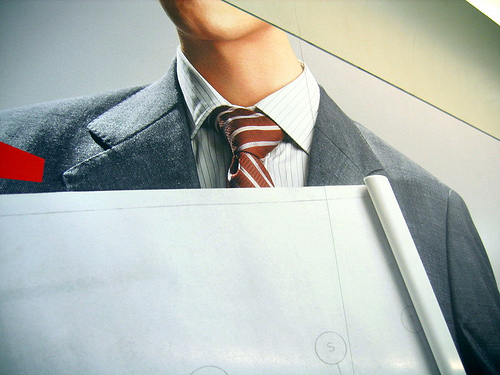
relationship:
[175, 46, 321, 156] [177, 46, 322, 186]
collar of shirt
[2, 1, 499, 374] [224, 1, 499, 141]
ad on a wall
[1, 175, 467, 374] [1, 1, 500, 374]
paper held by man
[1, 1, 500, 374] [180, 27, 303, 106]
man has a neck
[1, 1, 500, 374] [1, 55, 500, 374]
man in a suit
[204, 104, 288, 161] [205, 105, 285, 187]
knot on a tie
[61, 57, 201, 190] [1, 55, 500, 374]
lapel of suit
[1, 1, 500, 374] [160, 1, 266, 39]
man has a chin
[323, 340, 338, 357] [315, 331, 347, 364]
letter s in a circle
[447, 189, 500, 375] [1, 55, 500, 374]
sleeve of suit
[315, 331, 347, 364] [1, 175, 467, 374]
circle on a paper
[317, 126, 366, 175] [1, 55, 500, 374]
stiching on suit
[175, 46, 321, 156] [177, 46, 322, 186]
collar on shirt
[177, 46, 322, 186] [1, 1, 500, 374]
shirt worn by man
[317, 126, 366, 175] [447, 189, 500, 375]
stiching on sleeve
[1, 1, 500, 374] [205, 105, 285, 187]
man in a tie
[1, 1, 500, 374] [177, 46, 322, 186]
man in a shirt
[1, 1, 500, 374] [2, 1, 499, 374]
man on an ad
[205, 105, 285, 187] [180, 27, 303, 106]
tie around mans neck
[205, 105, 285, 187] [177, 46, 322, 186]
tie on a shirt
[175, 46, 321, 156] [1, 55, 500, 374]
collar on a suit